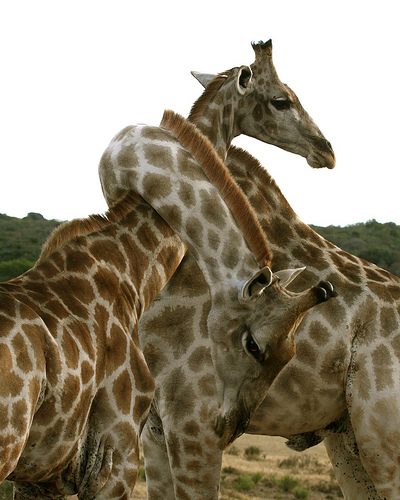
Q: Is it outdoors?
A: Yes, it is outdoors.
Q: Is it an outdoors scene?
A: Yes, it is outdoors.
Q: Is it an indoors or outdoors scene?
A: It is outdoors.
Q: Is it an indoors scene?
A: No, it is outdoors.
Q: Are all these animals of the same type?
A: Yes, all the animals are giraffes.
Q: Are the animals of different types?
A: No, all the animals are giraffes.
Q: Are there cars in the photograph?
A: No, there are no cars.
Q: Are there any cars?
A: No, there are no cars.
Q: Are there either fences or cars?
A: No, there are no cars or fences.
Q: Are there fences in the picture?
A: No, there are no fences.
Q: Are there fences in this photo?
A: No, there are no fences.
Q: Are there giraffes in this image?
A: Yes, there are giraffes.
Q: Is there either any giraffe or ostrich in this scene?
A: Yes, there are giraffes.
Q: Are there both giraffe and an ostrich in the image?
A: No, there are giraffes but no ostriches.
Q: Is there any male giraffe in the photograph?
A: Yes, there are male giraffes.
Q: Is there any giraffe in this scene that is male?
A: Yes, there are giraffes that are male.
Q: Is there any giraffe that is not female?
A: Yes, there are male giraffes.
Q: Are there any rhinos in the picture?
A: No, there are no rhinos.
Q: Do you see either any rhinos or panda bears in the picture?
A: No, there are no rhinos or panda bears.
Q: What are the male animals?
A: The animals are giraffes.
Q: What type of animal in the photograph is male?
A: The animal is giraffes.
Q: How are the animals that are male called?
A: The animals are giraffes.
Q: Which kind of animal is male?
A: The animal is giraffes.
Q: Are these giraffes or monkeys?
A: These are giraffes.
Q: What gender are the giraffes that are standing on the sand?
A: The giraffes are male.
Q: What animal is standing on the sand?
A: The giraffes are standing on the sand.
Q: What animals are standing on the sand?
A: The animals are giraffes.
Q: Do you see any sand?
A: Yes, there is sand.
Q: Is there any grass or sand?
A: Yes, there is sand.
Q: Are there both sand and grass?
A: Yes, there are both sand and grass.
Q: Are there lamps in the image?
A: No, there are no lamps.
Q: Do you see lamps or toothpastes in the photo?
A: No, there are no lamps or toothpastes.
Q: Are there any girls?
A: No, there are no girls.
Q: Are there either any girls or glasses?
A: No, there are no girls or glasses.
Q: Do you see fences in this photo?
A: No, there are no fences.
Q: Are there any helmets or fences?
A: No, there are no fences or helmets.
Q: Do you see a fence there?
A: No, there are no fences.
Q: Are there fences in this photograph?
A: No, there are no fences.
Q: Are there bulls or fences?
A: No, there are no fences or bulls.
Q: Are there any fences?
A: No, there are no fences.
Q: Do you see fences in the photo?
A: No, there are no fences.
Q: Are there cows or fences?
A: No, there are no fences or cows.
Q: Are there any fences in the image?
A: No, there are no fences.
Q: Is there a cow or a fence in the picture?
A: No, there are no fences or cows.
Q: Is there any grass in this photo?
A: Yes, there is grass.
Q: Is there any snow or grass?
A: Yes, there is grass.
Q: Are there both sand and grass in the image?
A: Yes, there are both grass and sand.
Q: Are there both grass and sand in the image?
A: Yes, there are both grass and sand.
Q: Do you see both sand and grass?
A: Yes, there are both grass and sand.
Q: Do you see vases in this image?
A: No, there are no vases.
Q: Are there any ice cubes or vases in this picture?
A: No, there are no vases or ice cubes.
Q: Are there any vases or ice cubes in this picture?
A: No, there are no vases or ice cubes.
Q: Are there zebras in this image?
A: No, there are no zebras.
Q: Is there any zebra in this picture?
A: No, there are no zebras.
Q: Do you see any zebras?
A: No, there are no zebras.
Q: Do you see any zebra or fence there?
A: No, there are no zebras or fences.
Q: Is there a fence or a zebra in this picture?
A: No, there are no zebras or fences.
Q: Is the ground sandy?
A: Yes, the ground is sandy.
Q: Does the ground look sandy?
A: Yes, the ground is sandy.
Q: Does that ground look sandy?
A: Yes, the ground is sandy.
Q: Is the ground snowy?
A: No, the ground is sandy.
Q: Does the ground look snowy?
A: No, the ground is sandy.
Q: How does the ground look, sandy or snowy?
A: The ground is sandy.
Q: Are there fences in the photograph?
A: No, there are no fences.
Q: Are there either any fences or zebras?
A: No, there are no fences or zebras.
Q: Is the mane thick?
A: Yes, the mane is thick.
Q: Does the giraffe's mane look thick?
A: Yes, the mane is thick.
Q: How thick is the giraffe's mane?
A: The mane is thick.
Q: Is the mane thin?
A: No, the mane is thick.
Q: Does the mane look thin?
A: No, the mane is thick.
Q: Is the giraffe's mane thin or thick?
A: The mane is thick.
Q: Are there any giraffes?
A: Yes, there is a giraffe.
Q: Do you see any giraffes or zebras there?
A: Yes, there is a giraffe.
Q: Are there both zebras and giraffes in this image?
A: No, there is a giraffe but no zebras.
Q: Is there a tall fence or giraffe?
A: Yes, there is a tall giraffe.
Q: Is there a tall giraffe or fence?
A: Yes, there is a tall giraffe.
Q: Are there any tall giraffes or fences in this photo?
A: Yes, there is a tall giraffe.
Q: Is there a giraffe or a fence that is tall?
A: Yes, the giraffe is tall.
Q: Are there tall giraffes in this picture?
A: Yes, there is a tall giraffe.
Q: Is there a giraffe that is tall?
A: Yes, there is a giraffe that is tall.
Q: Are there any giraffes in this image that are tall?
A: Yes, there is a giraffe that is tall.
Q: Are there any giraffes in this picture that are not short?
A: Yes, there is a tall giraffe.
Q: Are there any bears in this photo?
A: No, there are no bears.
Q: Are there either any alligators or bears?
A: No, there are no bears or alligators.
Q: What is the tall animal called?
A: The animal is a giraffe.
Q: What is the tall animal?
A: The animal is a giraffe.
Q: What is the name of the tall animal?
A: The animal is a giraffe.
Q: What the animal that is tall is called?
A: The animal is a giraffe.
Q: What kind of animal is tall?
A: The animal is a giraffe.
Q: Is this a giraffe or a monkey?
A: This is a giraffe.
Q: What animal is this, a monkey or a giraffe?
A: This is a giraffe.